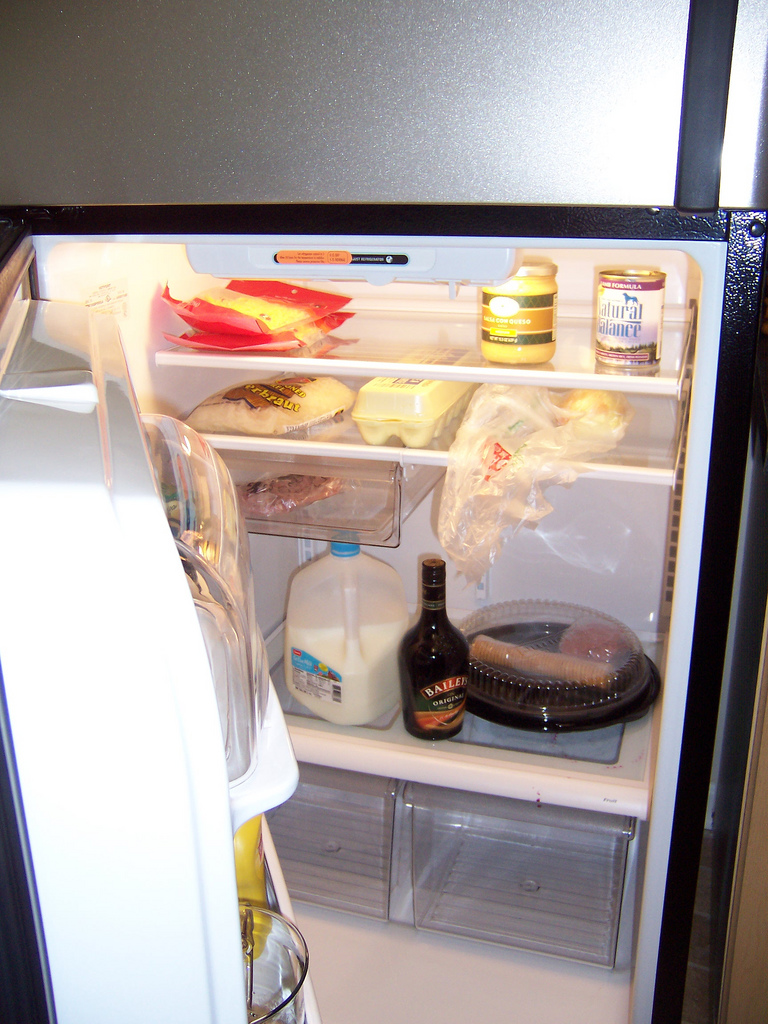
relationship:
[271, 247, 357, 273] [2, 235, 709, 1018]
orange sticker on white fridge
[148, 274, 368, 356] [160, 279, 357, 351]
bags have bags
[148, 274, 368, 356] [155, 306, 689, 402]
bags on top shelf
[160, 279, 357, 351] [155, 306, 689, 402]
bags on top shelf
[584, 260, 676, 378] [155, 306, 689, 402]
can sitting on top shelf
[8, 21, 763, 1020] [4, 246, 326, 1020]
door of refrigerator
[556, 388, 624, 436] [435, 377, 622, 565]
yellow onion in clear bag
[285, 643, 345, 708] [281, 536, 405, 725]
blue/white label on plastic jug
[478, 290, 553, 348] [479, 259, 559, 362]
green/orange label on glass jar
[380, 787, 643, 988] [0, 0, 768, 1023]
bin inside of door